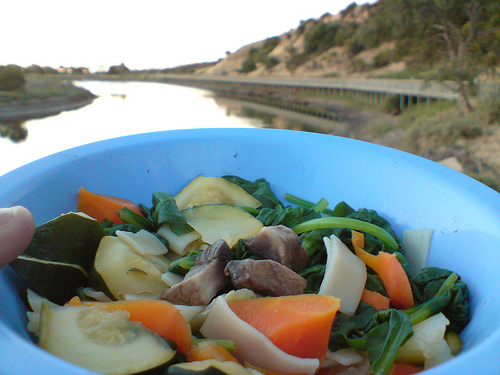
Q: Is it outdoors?
A: Yes, it is outdoors.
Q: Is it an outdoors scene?
A: Yes, it is outdoors.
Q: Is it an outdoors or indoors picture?
A: It is outdoors.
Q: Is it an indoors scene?
A: No, it is outdoors.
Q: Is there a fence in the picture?
A: No, there are no fences.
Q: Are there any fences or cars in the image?
A: No, there are no fences or cars.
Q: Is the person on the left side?
A: Yes, the person is on the left of the image.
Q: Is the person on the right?
A: No, the person is on the left of the image.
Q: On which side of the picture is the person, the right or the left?
A: The person is on the left of the image.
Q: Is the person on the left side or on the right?
A: The person is on the left of the image.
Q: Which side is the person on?
A: The person is on the left of the image.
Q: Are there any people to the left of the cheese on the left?
A: Yes, there is a person to the left of the cheese.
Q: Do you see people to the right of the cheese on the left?
A: No, the person is to the left of the cheese.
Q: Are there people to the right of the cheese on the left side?
A: No, the person is to the left of the cheese.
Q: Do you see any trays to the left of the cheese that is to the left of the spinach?
A: No, there is a person to the left of the cheese.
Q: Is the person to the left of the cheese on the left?
A: Yes, the person is to the left of the cheese.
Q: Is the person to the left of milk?
A: No, the person is to the left of the cheese.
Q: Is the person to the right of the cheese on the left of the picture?
A: No, the person is to the left of the cheese.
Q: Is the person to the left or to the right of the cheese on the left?
A: The person is to the left of the cheese.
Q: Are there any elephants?
A: No, there are no elephants.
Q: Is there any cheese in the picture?
A: Yes, there is cheese.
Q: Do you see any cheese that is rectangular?
A: Yes, there is rectangular cheese.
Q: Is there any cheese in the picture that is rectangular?
A: Yes, there is cheese that is rectangular.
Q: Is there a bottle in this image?
A: No, there are no bottles.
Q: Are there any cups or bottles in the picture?
A: No, there are no bottles or cups.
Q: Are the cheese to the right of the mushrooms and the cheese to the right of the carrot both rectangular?
A: Yes, both the cheese and the cheese are rectangular.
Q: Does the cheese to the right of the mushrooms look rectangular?
A: Yes, the cheese is rectangular.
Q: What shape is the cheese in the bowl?
A: The cheese is rectangular.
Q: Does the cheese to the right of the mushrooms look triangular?
A: No, the cheese is rectangular.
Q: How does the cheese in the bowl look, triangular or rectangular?
A: The cheese is rectangular.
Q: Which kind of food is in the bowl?
A: The food is cheese.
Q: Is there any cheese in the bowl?
A: Yes, there is cheese in the bowl.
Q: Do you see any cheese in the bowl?
A: Yes, there is cheese in the bowl.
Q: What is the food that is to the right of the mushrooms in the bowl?
A: The food is cheese.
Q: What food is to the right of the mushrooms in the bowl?
A: The food is cheese.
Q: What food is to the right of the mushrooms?
A: The food is cheese.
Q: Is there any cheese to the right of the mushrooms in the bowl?
A: Yes, there is cheese to the right of the mushrooms.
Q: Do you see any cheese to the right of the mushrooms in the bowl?
A: Yes, there is cheese to the right of the mushrooms.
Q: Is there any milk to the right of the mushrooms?
A: No, there is cheese to the right of the mushrooms.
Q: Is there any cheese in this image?
A: Yes, there is cheese.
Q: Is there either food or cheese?
A: Yes, there is cheese.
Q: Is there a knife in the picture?
A: No, there are no knives.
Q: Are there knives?
A: No, there are no knives.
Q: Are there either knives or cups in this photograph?
A: No, there are no knives or cups.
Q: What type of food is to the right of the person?
A: The food is cheese.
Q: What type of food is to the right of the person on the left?
A: The food is cheese.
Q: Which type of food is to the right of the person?
A: The food is cheese.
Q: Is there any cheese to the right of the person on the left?
A: Yes, there is cheese to the right of the person.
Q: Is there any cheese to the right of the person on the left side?
A: Yes, there is cheese to the right of the person.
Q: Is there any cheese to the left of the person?
A: No, the cheese is to the right of the person.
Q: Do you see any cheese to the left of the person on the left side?
A: No, the cheese is to the right of the person.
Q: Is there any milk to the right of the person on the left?
A: No, there is cheese to the right of the person.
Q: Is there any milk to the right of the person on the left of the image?
A: No, there is cheese to the right of the person.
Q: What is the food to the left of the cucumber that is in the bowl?
A: The food is cheese.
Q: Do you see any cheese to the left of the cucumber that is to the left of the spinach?
A: Yes, there is cheese to the left of the cucumber.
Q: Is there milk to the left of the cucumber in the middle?
A: No, there is cheese to the left of the cucumber.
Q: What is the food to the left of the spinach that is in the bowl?
A: The food is cheese.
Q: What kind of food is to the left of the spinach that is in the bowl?
A: The food is cheese.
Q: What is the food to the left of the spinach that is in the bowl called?
A: The food is cheese.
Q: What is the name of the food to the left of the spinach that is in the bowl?
A: The food is cheese.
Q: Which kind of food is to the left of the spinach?
A: The food is cheese.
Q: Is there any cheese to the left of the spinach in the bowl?
A: Yes, there is cheese to the left of the spinach.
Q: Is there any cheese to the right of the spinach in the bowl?
A: No, the cheese is to the left of the spinach.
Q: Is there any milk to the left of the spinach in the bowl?
A: No, there is cheese to the left of the spinach.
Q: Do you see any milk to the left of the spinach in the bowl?
A: No, there is cheese to the left of the spinach.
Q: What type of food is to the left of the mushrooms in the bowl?
A: The food is cheese.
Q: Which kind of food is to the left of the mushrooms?
A: The food is cheese.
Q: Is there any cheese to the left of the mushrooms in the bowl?
A: Yes, there is cheese to the left of the mushrooms.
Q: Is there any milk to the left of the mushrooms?
A: No, there is cheese to the left of the mushrooms.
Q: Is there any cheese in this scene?
A: Yes, there is cheese.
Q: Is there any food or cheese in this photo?
A: Yes, there is cheese.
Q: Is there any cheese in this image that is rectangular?
A: Yes, there is rectangular cheese.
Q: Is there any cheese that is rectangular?
A: Yes, there is cheese that is rectangular.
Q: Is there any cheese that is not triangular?
A: Yes, there is rectangular cheese.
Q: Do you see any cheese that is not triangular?
A: Yes, there is rectangular cheese.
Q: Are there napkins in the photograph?
A: No, there are no napkins.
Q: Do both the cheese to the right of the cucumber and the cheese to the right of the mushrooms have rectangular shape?
A: Yes, both the cheese and the cheese are rectangular.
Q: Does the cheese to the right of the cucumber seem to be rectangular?
A: Yes, the cheese is rectangular.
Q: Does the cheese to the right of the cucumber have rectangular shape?
A: Yes, the cheese is rectangular.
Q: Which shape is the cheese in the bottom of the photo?
A: The cheese is rectangular.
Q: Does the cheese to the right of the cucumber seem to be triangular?
A: No, the cheese is rectangular.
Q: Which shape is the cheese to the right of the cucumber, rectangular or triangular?
A: The cheese is rectangular.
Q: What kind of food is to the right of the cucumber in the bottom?
A: The food is cheese.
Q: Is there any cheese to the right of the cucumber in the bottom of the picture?
A: Yes, there is cheese to the right of the cucumber.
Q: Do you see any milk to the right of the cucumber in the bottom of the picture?
A: No, there is cheese to the right of the cucumber.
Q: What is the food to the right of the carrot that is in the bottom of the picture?
A: The food is cheese.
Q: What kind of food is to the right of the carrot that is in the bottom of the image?
A: The food is cheese.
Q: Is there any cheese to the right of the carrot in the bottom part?
A: Yes, there is cheese to the right of the carrot.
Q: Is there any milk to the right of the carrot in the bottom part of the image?
A: No, there is cheese to the right of the carrot.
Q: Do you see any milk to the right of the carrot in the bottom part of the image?
A: No, there is cheese to the right of the carrot.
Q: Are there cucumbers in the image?
A: Yes, there is a cucumber.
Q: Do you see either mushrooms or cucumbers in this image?
A: Yes, there is a cucumber.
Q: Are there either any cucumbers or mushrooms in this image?
A: Yes, there is a cucumber.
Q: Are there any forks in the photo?
A: No, there are no forks.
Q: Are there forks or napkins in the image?
A: No, there are no forks or napkins.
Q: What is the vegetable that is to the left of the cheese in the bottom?
A: The vegetable is a cucumber.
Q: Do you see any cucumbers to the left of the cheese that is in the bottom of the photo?
A: Yes, there is a cucumber to the left of the cheese.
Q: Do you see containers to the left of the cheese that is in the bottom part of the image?
A: No, there is a cucumber to the left of the cheese.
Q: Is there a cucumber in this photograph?
A: Yes, there is a cucumber.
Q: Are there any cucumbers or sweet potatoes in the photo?
A: Yes, there is a cucumber.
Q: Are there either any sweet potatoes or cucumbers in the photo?
A: Yes, there is a cucumber.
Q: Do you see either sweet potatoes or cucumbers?
A: Yes, there is a cucumber.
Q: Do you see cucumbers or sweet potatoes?
A: Yes, there is a cucumber.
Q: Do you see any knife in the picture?
A: No, there are no knives.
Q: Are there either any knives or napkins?
A: No, there are no knives or napkins.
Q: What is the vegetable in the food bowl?
A: The vegetable is a cucumber.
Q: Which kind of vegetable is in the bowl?
A: The vegetable is a cucumber.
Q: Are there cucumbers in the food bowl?
A: Yes, there is a cucumber in the bowl.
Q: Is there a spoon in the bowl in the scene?
A: No, there is a cucumber in the bowl.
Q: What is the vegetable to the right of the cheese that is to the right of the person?
A: The vegetable is a cucumber.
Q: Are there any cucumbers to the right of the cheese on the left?
A: Yes, there is a cucumber to the right of the cheese.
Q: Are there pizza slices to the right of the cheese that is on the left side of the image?
A: No, there is a cucumber to the right of the cheese.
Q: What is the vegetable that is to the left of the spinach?
A: The vegetable is a cucumber.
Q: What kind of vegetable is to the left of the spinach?
A: The vegetable is a cucumber.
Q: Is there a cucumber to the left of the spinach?
A: Yes, there is a cucumber to the left of the spinach.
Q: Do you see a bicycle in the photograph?
A: No, there are no bicycles.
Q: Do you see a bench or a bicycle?
A: No, there are no bicycles or benches.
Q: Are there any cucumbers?
A: Yes, there is a cucumber.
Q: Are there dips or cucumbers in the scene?
A: Yes, there is a cucumber.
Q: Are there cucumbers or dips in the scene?
A: Yes, there is a cucumber.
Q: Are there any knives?
A: No, there are no knives.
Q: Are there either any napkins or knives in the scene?
A: No, there are no knives or napkins.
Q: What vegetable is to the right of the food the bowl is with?
A: The vegetable is a cucumber.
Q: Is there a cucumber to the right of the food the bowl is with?
A: Yes, there is a cucumber to the right of the food.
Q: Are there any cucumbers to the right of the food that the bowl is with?
A: Yes, there is a cucumber to the right of the food.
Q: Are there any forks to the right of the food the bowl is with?
A: No, there is a cucumber to the right of the food.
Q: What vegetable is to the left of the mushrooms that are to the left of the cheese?
A: The vegetable is a cucumber.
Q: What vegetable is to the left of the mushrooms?
A: The vegetable is a cucumber.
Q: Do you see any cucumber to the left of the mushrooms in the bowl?
A: Yes, there is a cucumber to the left of the mushrooms.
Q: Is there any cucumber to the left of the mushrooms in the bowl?
A: Yes, there is a cucumber to the left of the mushrooms.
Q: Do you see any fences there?
A: No, there are no fences.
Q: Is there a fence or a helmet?
A: No, there are no fences or helmets.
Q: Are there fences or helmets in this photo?
A: No, there are no fences or helmets.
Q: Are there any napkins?
A: No, there are no napkins.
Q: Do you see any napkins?
A: No, there are no napkins.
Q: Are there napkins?
A: No, there are no napkins.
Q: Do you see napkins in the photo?
A: No, there are no napkins.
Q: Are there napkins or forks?
A: No, there are no napkins or forks.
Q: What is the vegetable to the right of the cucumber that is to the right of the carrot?
A: The vegetable is spinach.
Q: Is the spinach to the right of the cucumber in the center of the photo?
A: Yes, the spinach is to the right of the cucumber.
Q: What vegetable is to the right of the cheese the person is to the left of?
A: The vegetable is spinach.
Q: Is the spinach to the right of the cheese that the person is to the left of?
A: Yes, the spinach is to the right of the cheese.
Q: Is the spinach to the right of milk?
A: No, the spinach is to the right of the cheese.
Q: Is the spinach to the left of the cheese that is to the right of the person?
A: No, the spinach is to the right of the cheese.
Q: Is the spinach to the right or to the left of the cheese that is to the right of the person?
A: The spinach is to the right of the cheese.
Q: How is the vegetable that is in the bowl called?
A: The vegetable is spinach.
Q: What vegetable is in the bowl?
A: The vegetable is spinach.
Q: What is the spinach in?
A: The spinach is in the bowl.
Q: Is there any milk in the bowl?
A: No, there is spinach in the bowl.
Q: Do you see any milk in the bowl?
A: No, there is spinach in the bowl.